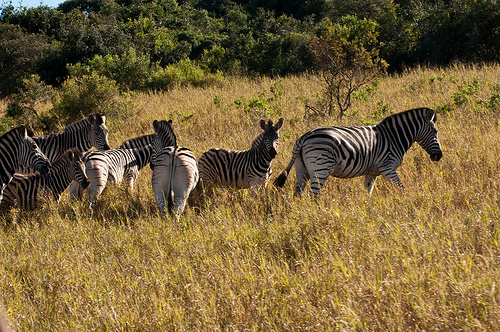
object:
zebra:
[274, 106, 442, 201]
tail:
[270, 133, 314, 188]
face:
[421, 114, 445, 161]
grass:
[0, 62, 498, 332]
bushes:
[140, 55, 226, 91]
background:
[1, 2, 500, 332]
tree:
[308, 35, 382, 119]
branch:
[304, 104, 319, 117]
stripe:
[304, 133, 346, 159]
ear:
[425, 108, 435, 122]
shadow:
[383, 62, 414, 75]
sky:
[0, 0, 87, 17]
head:
[412, 108, 441, 163]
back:
[291, 129, 339, 178]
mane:
[374, 107, 438, 133]